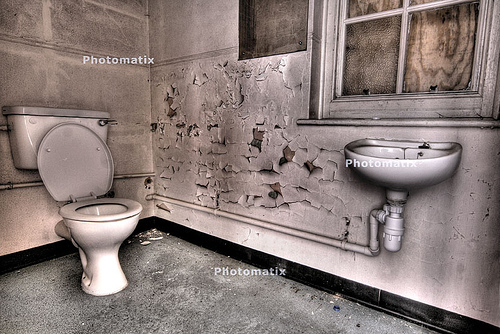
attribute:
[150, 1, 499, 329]
wall — old, cracked, dirty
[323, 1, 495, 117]
window — unopened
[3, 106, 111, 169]
tank — white, toilet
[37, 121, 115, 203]
toilet lid — white, opened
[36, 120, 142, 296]
toilet — white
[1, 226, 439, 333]
floor — concrete, grey-colored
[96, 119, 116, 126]
flush control — silver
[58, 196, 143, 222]
toilet seat — white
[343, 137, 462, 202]
sink — white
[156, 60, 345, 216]
paint — peeling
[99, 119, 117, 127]
handle — metallic